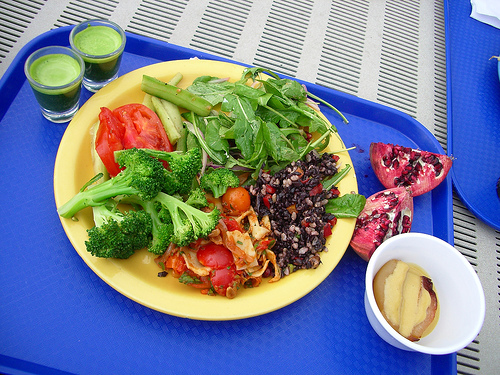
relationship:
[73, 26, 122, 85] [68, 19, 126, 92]
salad dressing in container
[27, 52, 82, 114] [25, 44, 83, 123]
beverage in container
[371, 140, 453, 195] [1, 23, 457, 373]
pomegranate on tray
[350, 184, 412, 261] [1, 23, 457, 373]
pomegranate on tray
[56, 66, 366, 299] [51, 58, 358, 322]
salad on plate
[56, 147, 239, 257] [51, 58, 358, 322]
broccoli on plate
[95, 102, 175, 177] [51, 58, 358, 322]
tomato on plate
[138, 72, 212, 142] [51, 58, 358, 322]
celery on plate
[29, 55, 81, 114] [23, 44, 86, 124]
beverage in glass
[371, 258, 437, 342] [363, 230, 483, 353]
dessert in bowl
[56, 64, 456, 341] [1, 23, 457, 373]
food on tray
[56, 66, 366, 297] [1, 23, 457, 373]
salad on tray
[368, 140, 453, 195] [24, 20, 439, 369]
pomegranate on tray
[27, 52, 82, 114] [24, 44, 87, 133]
beverage in shot glass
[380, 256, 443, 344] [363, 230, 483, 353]
dessert in bowl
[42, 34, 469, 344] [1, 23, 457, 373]
lunch on tray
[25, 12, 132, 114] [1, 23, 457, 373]
shot glasses on tray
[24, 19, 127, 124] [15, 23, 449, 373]
glasses in plate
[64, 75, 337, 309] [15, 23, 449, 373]
plate in plate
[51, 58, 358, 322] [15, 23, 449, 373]
plate in plate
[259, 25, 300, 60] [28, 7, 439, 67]
holes in stand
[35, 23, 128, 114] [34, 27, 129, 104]
glasses with juice